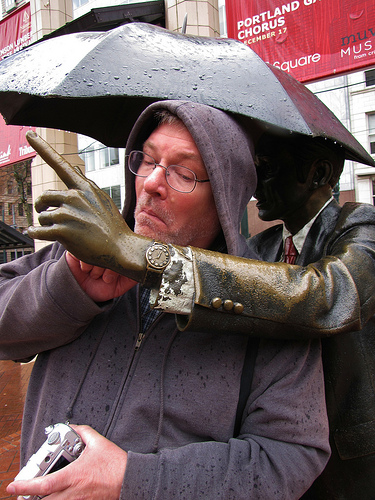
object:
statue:
[19, 110, 373, 500]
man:
[0, 91, 329, 497]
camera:
[10, 417, 80, 498]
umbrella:
[0, 12, 375, 176]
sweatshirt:
[0, 241, 336, 498]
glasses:
[125, 144, 211, 197]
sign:
[231, 0, 372, 65]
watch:
[141, 239, 173, 284]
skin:
[180, 199, 206, 239]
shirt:
[137, 288, 164, 337]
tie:
[280, 234, 300, 265]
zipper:
[130, 322, 148, 355]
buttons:
[212, 295, 223, 312]